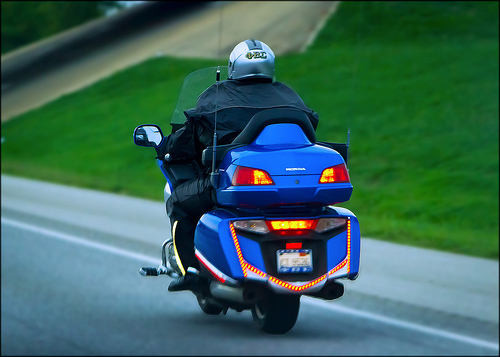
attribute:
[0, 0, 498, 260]
grass — green, a large patch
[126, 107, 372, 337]
motorcycle — blue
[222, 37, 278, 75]
helmet — metallic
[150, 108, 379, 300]
motorcycle — blue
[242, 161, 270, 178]
light — red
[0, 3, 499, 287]
grass — green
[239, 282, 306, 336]
tire — black, round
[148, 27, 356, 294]
jacket — black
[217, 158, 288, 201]
motorcycle lights — back light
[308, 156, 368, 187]
motorcycle lights — back light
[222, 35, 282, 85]
helmet — plastic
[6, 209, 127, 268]
line — white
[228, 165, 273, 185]
light — red and orange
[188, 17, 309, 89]
helmet — silver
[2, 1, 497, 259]
patch — green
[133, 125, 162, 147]
mirror — a side mirror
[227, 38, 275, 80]
helmet — silver